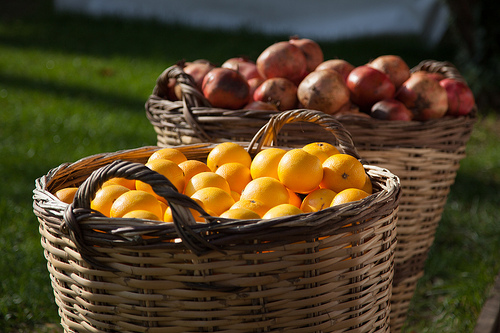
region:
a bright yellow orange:
[276, 148, 321, 191]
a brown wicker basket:
[30, 107, 395, 327]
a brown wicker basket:
[145, 56, 475, 326]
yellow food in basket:
[111, 141, 339, 231]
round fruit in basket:
[271, 132, 334, 189]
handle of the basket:
[83, 150, 185, 220]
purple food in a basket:
[181, 33, 461, 123]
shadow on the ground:
[38, 58, 128, 115]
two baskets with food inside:
[3, 54, 474, 329]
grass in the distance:
[61, 6, 210, 56]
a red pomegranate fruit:
[200, 66, 248, 105]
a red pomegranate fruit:
[255, 77, 294, 109]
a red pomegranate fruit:
[220, 56, 257, 78]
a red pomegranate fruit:
[171, 62, 209, 97]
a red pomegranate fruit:
[315, 59, 350, 79]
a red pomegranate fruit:
[286, 36, 321, 70]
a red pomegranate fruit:
[368, 55, 407, 82]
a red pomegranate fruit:
[398, 71, 448, 117]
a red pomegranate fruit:
[439, 76, 475, 116]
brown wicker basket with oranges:
[22, 102, 405, 330]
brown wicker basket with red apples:
[121, 40, 476, 325]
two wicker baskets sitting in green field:
[30, 30, 483, 322]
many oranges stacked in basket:
[71, 138, 392, 218]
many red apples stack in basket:
[185, 34, 464, 121]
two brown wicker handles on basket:
[64, 105, 370, 227]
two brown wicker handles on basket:
[145, 48, 467, 108]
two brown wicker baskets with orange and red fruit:
[32, 35, 478, 329]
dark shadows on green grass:
[6, 9, 499, 211]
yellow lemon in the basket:
[90, 127, 360, 225]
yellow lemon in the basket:
[270, 145, 315, 190]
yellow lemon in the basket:
[189, 184, 229, 214]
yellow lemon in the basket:
[106, 185, 161, 212]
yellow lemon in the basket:
[209, 140, 250, 169]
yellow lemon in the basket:
[317, 149, 364, 192]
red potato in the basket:
[346, 62, 392, 104]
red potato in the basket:
[251, 37, 301, 69]